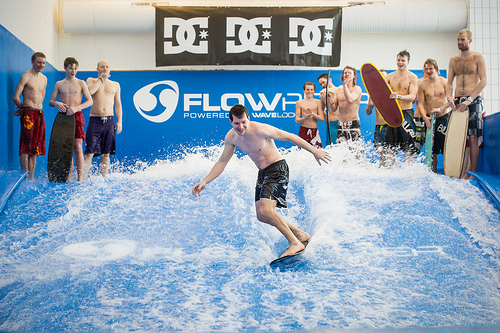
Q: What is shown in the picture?
A: A wave ramp.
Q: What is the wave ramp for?
A: Surfing.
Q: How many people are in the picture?
A: Eleven.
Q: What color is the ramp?
A: Blue.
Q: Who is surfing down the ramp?
A: A man.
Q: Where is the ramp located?
A: At a waterpark.